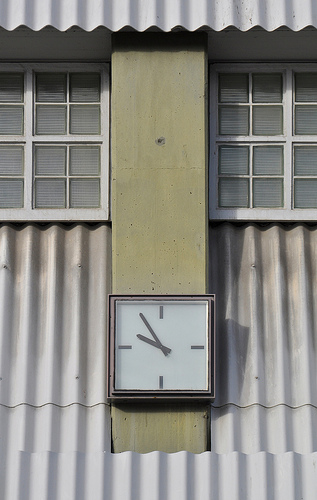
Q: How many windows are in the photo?
A: Two.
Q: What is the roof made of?
A: Metal.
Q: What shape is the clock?
A: Square.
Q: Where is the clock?
A: Wall.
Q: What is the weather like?
A: Sunshine.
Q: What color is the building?
A: Grey.